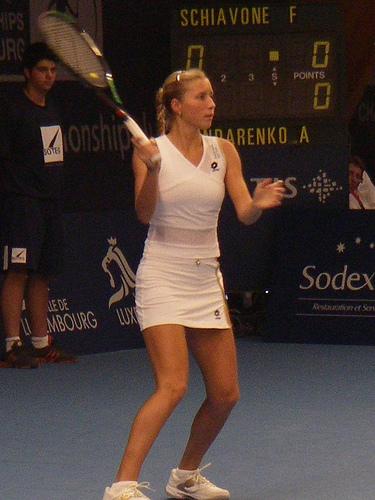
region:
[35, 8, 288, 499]
The woman is holding a tennis racket.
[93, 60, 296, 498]
The woman's knees are slightly bent.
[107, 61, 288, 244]
The woman's hair is braided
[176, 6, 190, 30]
The letter is yellow.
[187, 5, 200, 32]
The letter is yellow.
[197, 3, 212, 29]
The letter is yellow.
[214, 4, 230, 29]
The letter is yellow.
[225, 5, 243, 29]
The letter is yellow.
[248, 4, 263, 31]
The letter is yellow.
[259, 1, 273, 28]
The letter is yellow.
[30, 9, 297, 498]
the woman plays tennis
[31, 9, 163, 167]
the woman holds a tennis racquet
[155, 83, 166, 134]
the woman has her hair pulled back in a braided ponytail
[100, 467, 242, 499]
the woman is wearing white tennis shoes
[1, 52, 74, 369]
a man stands behind the woman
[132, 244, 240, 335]
the woman wears a tennis skirt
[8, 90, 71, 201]
the man wears a dark t-shirt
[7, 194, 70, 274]
the man is wearing shorts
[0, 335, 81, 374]
the mans shoes are black with orange stripes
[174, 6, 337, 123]
the scoreboard is behind the woman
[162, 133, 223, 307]
A white dress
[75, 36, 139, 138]
A tennis racket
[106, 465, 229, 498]
White shoes on the legs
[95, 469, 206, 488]
A pair of white socks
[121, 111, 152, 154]
A white handle on the racket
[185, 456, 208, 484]
Shoe lace on the shoe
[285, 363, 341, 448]
A tennis court field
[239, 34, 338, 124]
A screen in the background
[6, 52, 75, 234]
A man standing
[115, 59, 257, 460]
A woman playing tennis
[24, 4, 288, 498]
a woman with a racket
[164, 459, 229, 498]
white shoes with white laces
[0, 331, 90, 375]
black shoes with red stripes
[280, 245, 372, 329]
white letters on the wall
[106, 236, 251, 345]
a white skort with black symbol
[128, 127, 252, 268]
a white shirt with black symbol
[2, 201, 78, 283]
black shorts with white square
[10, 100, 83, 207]
black shirt with white square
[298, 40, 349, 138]
0 points on the scoreboard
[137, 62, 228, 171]
hair in a braid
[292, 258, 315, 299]
The letter is white.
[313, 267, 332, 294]
The letter is white.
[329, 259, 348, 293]
The letter is white.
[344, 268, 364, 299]
The letter is white.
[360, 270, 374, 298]
The letter is white.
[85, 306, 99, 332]
The letter is white.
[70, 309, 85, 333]
The letter is white.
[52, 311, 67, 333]
The letter is white.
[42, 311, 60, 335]
The letter is white.